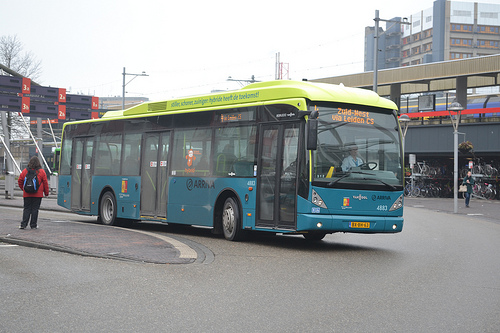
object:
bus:
[53, 77, 409, 242]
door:
[69, 135, 101, 216]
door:
[139, 126, 177, 219]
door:
[255, 121, 303, 232]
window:
[90, 130, 126, 175]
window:
[168, 125, 217, 178]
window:
[210, 124, 258, 178]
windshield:
[310, 103, 403, 193]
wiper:
[363, 175, 400, 193]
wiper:
[325, 164, 379, 188]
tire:
[96, 188, 121, 227]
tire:
[217, 193, 245, 242]